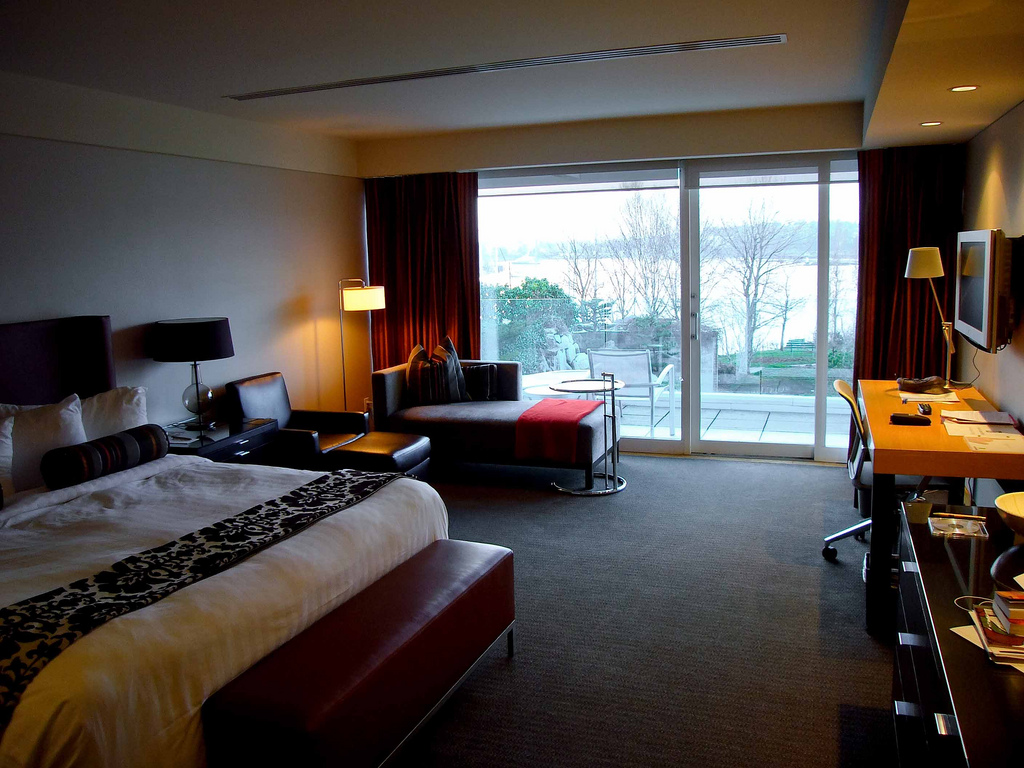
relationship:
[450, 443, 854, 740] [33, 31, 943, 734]
carpet in room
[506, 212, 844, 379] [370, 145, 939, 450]
trees outside window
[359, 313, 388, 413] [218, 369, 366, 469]
pole near chair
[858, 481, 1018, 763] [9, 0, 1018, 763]
chest in room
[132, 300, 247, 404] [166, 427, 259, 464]
table lamp beside table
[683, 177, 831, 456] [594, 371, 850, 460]
door next patio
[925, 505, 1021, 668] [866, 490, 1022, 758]
literature on chest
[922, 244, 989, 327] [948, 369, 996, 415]
television screen affixed to wall